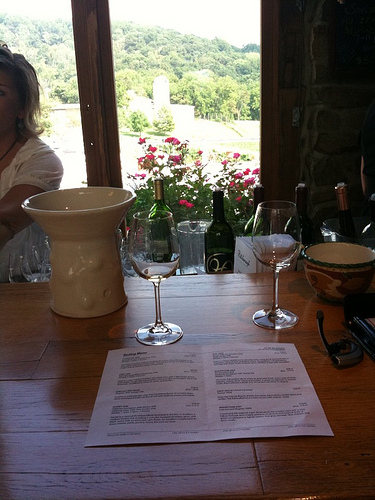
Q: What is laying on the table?
A: A menu.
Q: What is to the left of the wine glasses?
A: White ceramic vase.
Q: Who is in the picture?
A: Blond haired woman.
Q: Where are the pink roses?
A: Outside the window.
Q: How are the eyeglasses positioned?
A: Upside down and open.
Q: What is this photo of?
A: A table.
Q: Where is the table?
A: In a restaurant.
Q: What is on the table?
A: A paper.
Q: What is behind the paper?
A: Wine glasses.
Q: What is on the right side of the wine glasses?
A: A bowl.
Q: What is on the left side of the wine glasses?
A: A vase.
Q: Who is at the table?
A: A woman.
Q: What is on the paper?
A: Lettering.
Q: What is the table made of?
A: Wood.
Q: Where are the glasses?
A: Table.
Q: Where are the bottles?
A: Beside the table.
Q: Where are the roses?
A: Outside the window.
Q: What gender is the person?
A: Female.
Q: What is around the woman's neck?
A: Necklace.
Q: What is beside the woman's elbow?
A: Glasses.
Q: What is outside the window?
A: Trees.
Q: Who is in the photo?
A: A woman.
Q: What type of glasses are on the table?
A: Wine glasses.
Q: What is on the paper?
A: Menu.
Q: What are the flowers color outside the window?
A: Pink.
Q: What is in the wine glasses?
A: Nothing.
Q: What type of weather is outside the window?
A: Sunny.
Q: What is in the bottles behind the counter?
A: Wine.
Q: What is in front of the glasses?
A: A piece of paper.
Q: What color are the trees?
A: Green.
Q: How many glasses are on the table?
A: Two.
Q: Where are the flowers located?
A: Other side of the window.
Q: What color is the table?
A: Brown.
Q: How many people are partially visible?
A: One.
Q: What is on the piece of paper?
A: Words.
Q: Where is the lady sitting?
A: Off to the left.